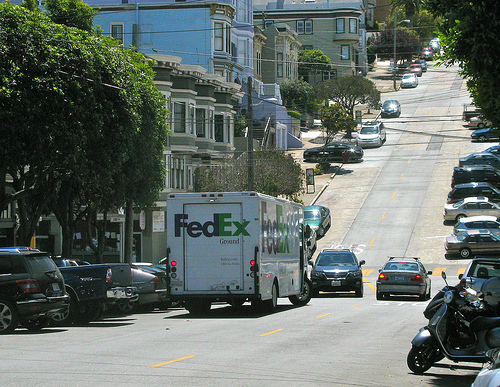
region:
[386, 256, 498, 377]
Motorcycle parked on street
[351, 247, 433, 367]
Car stopped on a street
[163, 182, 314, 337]
Fedex Ground truck on street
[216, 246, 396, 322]
Suv passing a Fedex truck on the street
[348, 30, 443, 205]
Cars parked a down sloping street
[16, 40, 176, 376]
Big tree on street sidewalk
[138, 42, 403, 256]
White and green homes on side of street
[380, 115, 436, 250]
Dashed dividing line on street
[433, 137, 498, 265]
Cars parked along a street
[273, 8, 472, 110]
Beige and brown housing building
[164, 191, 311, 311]
Fed Ex delivery truck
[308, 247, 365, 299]
Fron end of a dark colored car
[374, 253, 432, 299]
Rear end of a small silver car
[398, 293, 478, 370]
Front part of a motorcycle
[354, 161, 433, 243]
Two lane roadway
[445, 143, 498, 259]
Row of parked cars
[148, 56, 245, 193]
Front top portion of victorian style housing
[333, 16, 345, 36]
Rectangular shaped trimed exterior of a window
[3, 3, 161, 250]
Row of three full green trees in front of buildings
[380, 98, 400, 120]
Sun beaming on a parked car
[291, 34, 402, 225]
the road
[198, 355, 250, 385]
the road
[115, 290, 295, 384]
the road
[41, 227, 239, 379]
the road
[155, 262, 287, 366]
the road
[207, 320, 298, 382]
the road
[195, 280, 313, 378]
the road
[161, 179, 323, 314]
A FedEx white truck.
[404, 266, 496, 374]
A silver moped.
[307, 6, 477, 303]
An upward slope of road.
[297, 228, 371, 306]
A dark colored vehicle in front of a FedEx truck.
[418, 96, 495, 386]
Parked vehicles on the side of the road.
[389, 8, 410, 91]
A street light.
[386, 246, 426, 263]
A rack on top of a silver car.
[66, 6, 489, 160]
Power lines hanging above the road.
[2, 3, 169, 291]
A row of trees in front of the building.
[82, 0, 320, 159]
A light blue colored house.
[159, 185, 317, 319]
the truck is a FedEx truck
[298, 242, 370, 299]
the SUV is black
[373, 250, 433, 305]
the car is white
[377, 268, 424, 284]
the car's brake lights are red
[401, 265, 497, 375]
the scooter is parked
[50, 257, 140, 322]
the truck is black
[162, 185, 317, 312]
the truck is double parked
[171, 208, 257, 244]
FedEX is blue and green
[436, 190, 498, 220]
the car has a sun roof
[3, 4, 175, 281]
the trees are lush and green